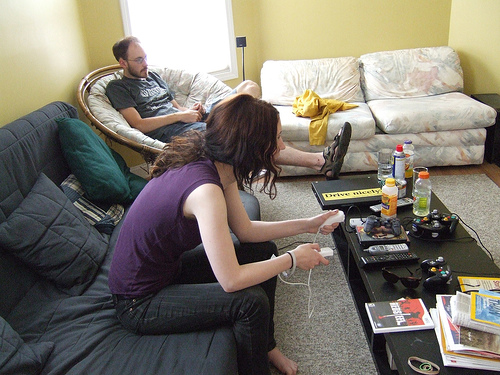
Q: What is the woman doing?
A: Playing WII.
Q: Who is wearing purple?
A: Woman.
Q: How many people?
A: Two.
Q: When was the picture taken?
A: Daytime.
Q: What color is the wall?
A: Tan.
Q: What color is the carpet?
A: Gray.